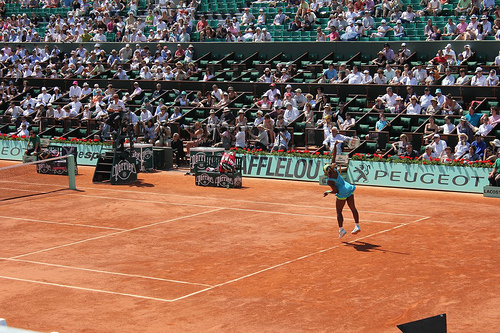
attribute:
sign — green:
[241, 151, 496, 215]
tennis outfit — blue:
[330, 176, 353, 198]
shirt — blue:
[331, 178, 350, 192]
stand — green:
[94, 113, 140, 179]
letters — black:
[246, 147, 319, 181]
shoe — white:
[336, 227, 347, 239]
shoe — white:
[350, 224, 361, 234]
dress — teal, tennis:
[318, 163, 356, 203]